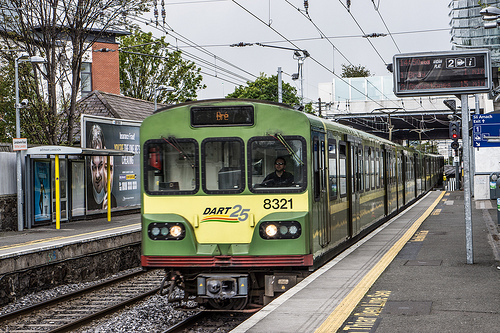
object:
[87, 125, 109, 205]
smiling woman